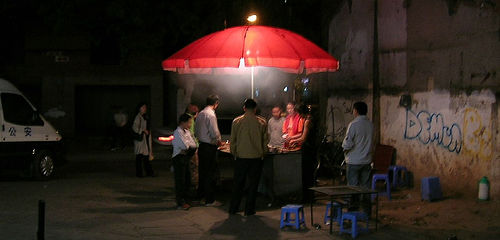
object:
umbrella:
[163, 25, 342, 101]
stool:
[277, 203, 309, 232]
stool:
[339, 211, 369, 239]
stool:
[322, 197, 355, 225]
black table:
[304, 184, 381, 234]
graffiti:
[402, 106, 463, 154]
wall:
[323, 0, 500, 200]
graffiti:
[461, 109, 494, 161]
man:
[227, 97, 272, 218]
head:
[240, 98, 259, 112]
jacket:
[340, 114, 375, 165]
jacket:
[229, 112, 271, 160]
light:
[241, 13, 261, 25]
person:
[191, 94, 222, 207]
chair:
[371, 174, 393, 202]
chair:
[386, 165, 413, 192]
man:
[340, 100, 378, 219]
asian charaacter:
[7, 126, 34, 138]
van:
[2, 74, 69, 183]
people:
[168, 91, 318, 216]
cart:
[217, 139, 305, 207]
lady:
[127, 101, 157, 180]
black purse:
[130, 127, 145, 143]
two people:
[282, 101, 315, 202]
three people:
[268, 100, 318, 203]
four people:
[171, 94, 268, 217]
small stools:
[335, 209, 371, 240]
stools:
[323, 200, 372, 239]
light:
[234, 26, 263, 44]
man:
[168, 113, 198, 210]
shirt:
[168, 127, 201, 159]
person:
[278, 101, 307, 150]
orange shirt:
[280, 113, 308, 153]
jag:
[472, 174, 490, 205]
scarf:
[283, 114, 299, 137]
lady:
[107, 104, 129, 153]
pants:
[113, 124, 128, 150]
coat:
[130, 112, 156, 157]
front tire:
[30, 148, 62, 182]